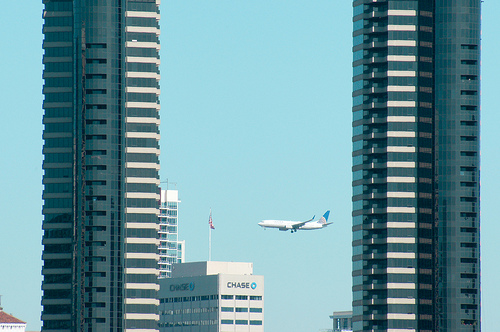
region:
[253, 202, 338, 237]
white airplane in the sky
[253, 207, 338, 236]
large white metal aircraft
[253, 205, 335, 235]
airplane with red white and blue tail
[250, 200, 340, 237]
big flying metal aircraft carrying people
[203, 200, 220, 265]
flag on metal pole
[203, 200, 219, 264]
American flag on tall metal flagpole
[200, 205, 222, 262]
flagpole on top of bank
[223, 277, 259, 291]
name logo of large bank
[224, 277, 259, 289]
Chase bank logo with blue symbol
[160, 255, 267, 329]
tall bank next to an even taller skyscraper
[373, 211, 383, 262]
part of a window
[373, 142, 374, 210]
edge of a building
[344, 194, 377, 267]
side of a building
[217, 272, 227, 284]
top of a building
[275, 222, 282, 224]
part of a plane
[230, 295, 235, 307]
window of a building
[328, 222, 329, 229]
tip of a plane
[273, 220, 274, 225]
edge of a plane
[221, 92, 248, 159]
part of the sky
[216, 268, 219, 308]
edge of a wall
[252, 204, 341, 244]
Plane in the sky.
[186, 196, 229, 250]
Flag on the building.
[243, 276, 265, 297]
Chase logo on the building.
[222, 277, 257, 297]
Chase on the building.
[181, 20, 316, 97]
The sky is blue.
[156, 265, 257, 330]
The building is white.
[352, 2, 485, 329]
The building is tall.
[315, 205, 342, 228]
Tail of the plane is blue.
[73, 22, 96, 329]
Brown and grey line on the building.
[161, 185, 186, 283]
The building is white and glass.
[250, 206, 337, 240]
a plane between the buildings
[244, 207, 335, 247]
a plane flying in the air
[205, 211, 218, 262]
a flag on the building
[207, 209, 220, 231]
an american flag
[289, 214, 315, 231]
the wing of the plane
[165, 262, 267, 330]
the chase building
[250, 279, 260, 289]
the blue logo for chase bank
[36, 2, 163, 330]
a tall glass building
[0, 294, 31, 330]
the red roof of a building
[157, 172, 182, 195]
crane on the building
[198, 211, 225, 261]
American flag on pole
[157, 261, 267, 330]
high-rise Chase building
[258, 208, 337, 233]
airplane with mostly blue tail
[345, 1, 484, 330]
high rise building with reflective surface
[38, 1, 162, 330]
high-rise building with reflective surface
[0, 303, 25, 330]
residence with tile roof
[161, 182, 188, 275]
high rise building with antenna on top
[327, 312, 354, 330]
building in an urban area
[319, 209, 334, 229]
tail of the airplane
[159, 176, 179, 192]
transmission antenna on top of the building